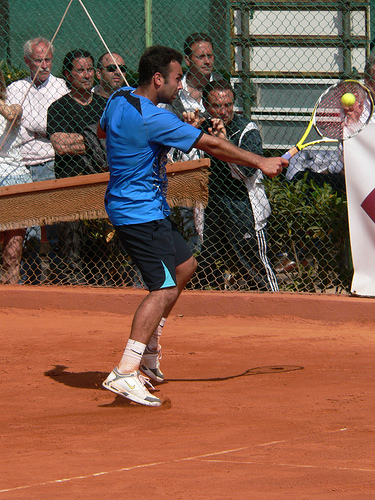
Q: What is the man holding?
A: Tennis racquet.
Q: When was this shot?
A: Daytime.